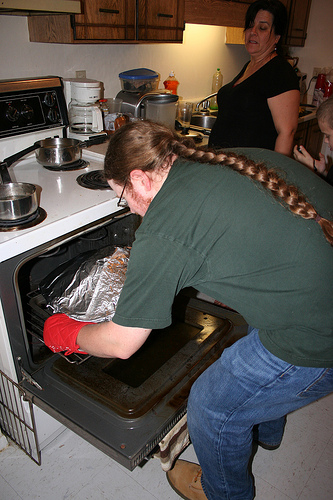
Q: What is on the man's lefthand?
A: A red oven mitt.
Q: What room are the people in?
A: Kitchen.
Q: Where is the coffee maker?
A: On the counter next to the stove.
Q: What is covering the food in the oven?
A: Aluminum foil.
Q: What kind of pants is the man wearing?
A: Blue jeans.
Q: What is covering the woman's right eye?
A: Her hair.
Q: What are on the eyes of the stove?
A: Pots.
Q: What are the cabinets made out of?
A: Wood.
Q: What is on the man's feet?
A: Brown shoes.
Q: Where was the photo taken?
A: In a kitchen.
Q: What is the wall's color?
A: White.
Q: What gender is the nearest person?
A: Male.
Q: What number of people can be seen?
A: Three.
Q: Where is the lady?
A: Next to the guy.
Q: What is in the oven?
A: Food.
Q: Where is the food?
A: In the oven.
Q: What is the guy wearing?
A: An oven mitt.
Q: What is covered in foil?
A: The food.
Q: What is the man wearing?
A: Glasses.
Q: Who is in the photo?
A: Three people.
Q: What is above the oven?
A: Stove.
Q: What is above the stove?
A: Cabinets.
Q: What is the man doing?
A: Taking something out of the oven.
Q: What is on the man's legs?
A: Blue jeans.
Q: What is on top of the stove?
A: Pots.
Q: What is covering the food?
A: Aluminum foil.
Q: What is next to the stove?
A: A white coffee maker.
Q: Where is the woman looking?
A: At the man taking the food out.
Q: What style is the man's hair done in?
A: Braid.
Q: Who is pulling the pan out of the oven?
A: The man.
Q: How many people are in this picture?
A: 3.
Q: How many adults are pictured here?
A: 2.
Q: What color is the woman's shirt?
A: Black.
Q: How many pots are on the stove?
A: 3.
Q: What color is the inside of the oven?
A: Gray.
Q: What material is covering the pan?
A: Foil.